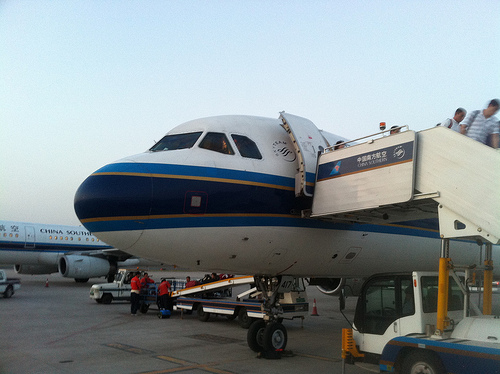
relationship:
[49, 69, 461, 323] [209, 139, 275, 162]
plane has window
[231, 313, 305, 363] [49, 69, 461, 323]
wheel of plane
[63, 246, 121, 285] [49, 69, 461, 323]
engine of plane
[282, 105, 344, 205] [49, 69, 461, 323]
door of plane